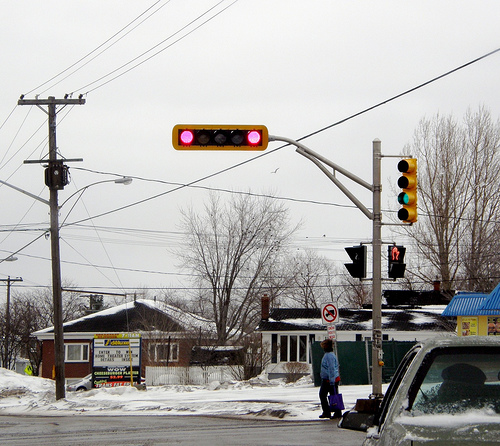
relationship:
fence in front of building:
[141, 362, 247, 387] [28, 294, 246, 394]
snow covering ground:
[129, 384, 249, 404] [63, 398, 293, 443]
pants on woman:
[310, 376, 372, 426] [266, 328, 380, 436]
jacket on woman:
[307, 339, 368, 377] [260, 332, 366, 418]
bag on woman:
[316, 370, 359, 420] [310, 330, 374, 438]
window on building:
[51, 338, 102, 368] [32, 291, 257, 413]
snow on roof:
[108, 292, 202, 319] [57, 279, 262, 330]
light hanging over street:
[167, 122, 273, 152] [0, 407, 380, 444]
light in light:
[397, 159, 407, 172] [395, 156, 417, 224]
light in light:
[395, 176, 412, 204] [395, 156, 417, 224]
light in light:
[397, 193, 411, 207] [395, 156, 417, 224]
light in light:
[394, 207, 410, 221] [395, 156, 417, 224]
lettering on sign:
[95, 347, 139, 361] [90, 332, 145, 391]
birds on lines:
[294, 229, 325, 256] [57, 217, 497, 254]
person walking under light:
[314, 334, 347, 421] [170, 120, 271, 153]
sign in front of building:
[90, 332, 145, 391] [28, 294, 246, 394]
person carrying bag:
[318, 338, 345, 418] [325, 390, 347, 411]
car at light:
[362, 334, 484, 439] [164, 115, 270, 155]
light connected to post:
[167, 122, 273, 152] [270, 133, 415, 397]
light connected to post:
[394, 155, 420, 224] [270, 133, 415, 397]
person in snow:
[318, 338, 345, 418] [1, 362, 393, 418]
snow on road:
[0, 364, 391, 420] [4, 411, 357, 443]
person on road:
[314, 334, 347, 421] [6, 406, 386, 442]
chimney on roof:
[244, 284, 295, 329] [239, 281, 467, 334]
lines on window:
[276, 333, 301, 353] [252, 313, 340, 364]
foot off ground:
[304, 414, 350, 424] [195, 398, 384, 443]